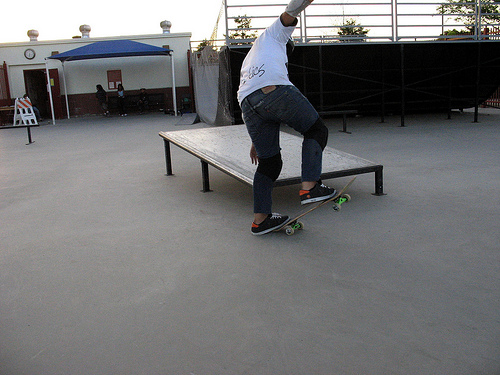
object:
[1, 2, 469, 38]
sky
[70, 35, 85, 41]
vents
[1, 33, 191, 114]
concrete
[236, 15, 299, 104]
shirt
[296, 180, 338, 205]
sneaker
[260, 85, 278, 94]
leather patch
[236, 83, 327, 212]
blue jeans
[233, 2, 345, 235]
man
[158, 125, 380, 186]
wooden surface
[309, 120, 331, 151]
kneepads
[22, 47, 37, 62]
clock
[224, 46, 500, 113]
wall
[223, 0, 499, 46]
fence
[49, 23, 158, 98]
tent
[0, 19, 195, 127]
building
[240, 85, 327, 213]
jeans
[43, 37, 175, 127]
blue tent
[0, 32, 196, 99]
wall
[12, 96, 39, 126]
sign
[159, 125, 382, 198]
feature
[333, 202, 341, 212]
green wheel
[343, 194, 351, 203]
green wheel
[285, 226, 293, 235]
green wheel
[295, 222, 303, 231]
green wheel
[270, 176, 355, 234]
skateboard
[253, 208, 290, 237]
sneakers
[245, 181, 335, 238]
feet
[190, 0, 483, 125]
bleachers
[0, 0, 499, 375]
park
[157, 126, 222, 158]
light reflection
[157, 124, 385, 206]
ramp